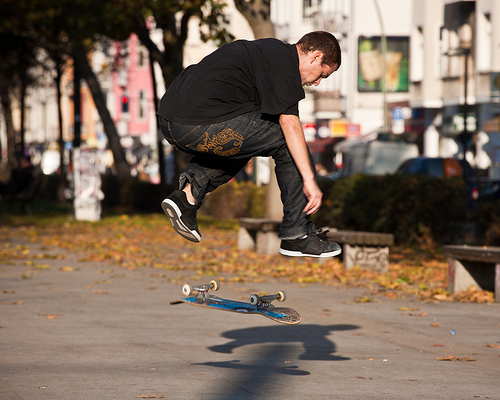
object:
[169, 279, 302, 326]
skateboard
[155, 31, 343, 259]
skateboarder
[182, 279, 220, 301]
truck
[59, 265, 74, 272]
leaf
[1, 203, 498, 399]
ground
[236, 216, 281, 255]
bench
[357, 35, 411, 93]
sign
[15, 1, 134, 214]
tree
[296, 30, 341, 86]
head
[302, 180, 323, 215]
hand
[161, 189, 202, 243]
foot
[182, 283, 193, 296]
wheel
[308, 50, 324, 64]
ear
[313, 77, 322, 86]
nose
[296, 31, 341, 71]
hair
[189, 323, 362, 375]
shadow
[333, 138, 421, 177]
vehicle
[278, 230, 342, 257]
shoe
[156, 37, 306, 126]
shirt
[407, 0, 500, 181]
building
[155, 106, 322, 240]
jeans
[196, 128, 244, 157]
design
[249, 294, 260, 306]
wheel